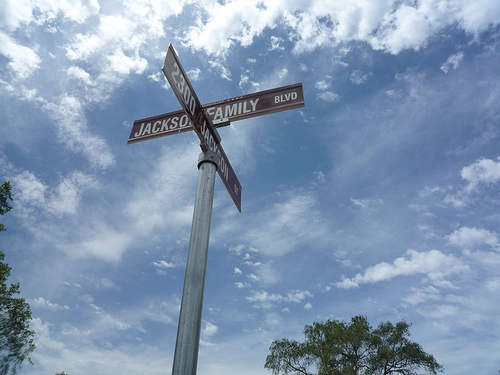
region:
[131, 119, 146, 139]
alphabet on a plate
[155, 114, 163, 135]
alphabet on a plate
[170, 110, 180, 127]
alphabet on a plate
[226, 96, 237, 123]
alphabet on a plate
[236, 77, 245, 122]
alphabet on a plate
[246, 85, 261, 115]
alphabet on a plate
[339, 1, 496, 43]
The clouds are white.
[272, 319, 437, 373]
The leaves are green.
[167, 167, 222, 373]
The pole is tall.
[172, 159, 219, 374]
The pole is made of metal.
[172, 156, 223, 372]
the pole is gray in color.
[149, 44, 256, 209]
The sign is brown and white.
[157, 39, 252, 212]
The sign is in English.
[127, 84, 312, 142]
The sign writing is in white.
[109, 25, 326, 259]
street sign on pole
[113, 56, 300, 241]
street sign on pole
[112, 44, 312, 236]
street sign on pole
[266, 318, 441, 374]
A tree near the street signs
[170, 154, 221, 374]
A post connected to the street signs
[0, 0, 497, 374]
A blue sky above the trees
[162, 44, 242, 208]
A green street sign connected to the pole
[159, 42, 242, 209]
The street sign is rectangular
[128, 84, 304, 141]
A street sign for Jackson Family Boulevard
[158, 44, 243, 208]
A street sign for 2300 Jackson Street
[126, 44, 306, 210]
Street signs above the road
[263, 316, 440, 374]
Leaves on the tree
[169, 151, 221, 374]
The post holding the street signs is silver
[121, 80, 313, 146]
A Brown street sign says Jackson Family BLVD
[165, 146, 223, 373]
A metal pole that holds a sign.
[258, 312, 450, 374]
The branches of a tree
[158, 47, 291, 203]
a sign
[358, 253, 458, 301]
the clouds are white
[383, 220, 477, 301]
clouds in the sky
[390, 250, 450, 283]
a white cloud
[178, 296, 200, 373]
a grey pole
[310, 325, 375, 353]
a green tree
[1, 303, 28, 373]
leaves are green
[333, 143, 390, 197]
the sky is blue and cloudy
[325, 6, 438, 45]
white clouds in the sky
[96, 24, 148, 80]
the white clouds in the sky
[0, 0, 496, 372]
the clouds are white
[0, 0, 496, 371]
the clouds in the sky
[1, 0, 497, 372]
the clouds in the blue sky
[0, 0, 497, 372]
the white clouds in the blue sky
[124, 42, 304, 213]
the street signs are brown and white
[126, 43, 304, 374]
the street signs on the pole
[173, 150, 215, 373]
the pole is gray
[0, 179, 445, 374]
the leaves are green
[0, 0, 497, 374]
the trees under the blue sky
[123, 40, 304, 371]
brown and silver road sign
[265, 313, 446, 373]
green tree top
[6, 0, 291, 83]
glowing puffy white clouds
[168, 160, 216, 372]
smooth metal sign pole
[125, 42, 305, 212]
brown criss-crossing signs with white letters